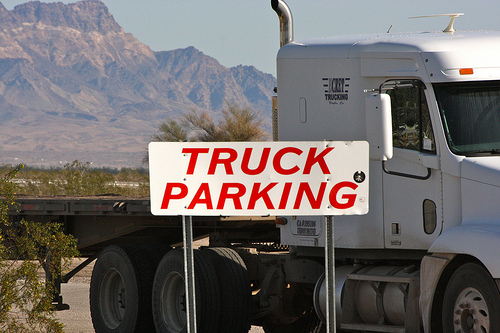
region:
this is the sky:
[187, 5, 231, 34]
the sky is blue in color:
[302, 4, 337, 29]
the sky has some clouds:
[226, 7, 268, 54]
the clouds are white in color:
[143, 5, 188, 31]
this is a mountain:
[1, 4, 256, 121]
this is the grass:
[32, 165, 98, 188]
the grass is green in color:
[57, 163, 117, 189]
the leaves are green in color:
[6, 220, 67, 281]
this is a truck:
[31, 3, 498, 324]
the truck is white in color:
[478, 165, 493, 231]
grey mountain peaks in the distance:
[1, 3, 263, 115]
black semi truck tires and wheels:
[81, 241, 252, 331]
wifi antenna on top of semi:
[398, 8, 474, 44]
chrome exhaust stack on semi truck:
[263, 1, 301, 48]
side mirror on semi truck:
[362, 83, 438, 184]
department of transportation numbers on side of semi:
[288, 218, 323, 239]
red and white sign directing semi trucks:
[139, 133, 379, 220]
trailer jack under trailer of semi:
[35, 228, 75, 316]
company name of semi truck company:
[316, 72, 359, 111]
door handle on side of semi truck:
[381, 214, 411, 244]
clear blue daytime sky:
[102, 0, 497, 82]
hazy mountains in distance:
[0, 0, 276, 167]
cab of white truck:
[278, 28, 498, 275]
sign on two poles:
[150, 141, 369, 331]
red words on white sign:
[149, 140, 368, 215]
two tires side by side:
[153, 245, 253, 331]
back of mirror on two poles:
[369, 76, 431, 180]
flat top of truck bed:
[0, 194, 276, 258]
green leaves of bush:
[0, 181, 77, 331]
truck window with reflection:
[385, 78, 435, 152]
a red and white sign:
[122, 118, 398, 332]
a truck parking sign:
[122, 120, 421, 331]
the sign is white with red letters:
[127, 108, 409, 331]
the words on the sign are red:
[126, 132, 391, 242]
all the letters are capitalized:
[118, 127, 381, 223]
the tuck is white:
[252, 23, 498, 331]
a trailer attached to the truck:
[0, 180, 263, 328]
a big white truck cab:
[256, 0, 493, 330]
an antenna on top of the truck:
[400, 7, 472, 38]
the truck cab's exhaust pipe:
[261, 2, 308, 144]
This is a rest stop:
[30, 9, 438, 327]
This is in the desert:
[22, 30, 406, 327]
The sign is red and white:
[133, 101, 353, 250]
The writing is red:
[152, 110, 376, 261]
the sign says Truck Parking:
[84, 120, 401, 322]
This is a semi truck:
[244, 9, 499, 273]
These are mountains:
[4, 14, 201, 155]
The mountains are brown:
[22, 22, 242, 175]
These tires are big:
[90, 234, 210, 319]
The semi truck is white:
[294, 28, 461, 169]